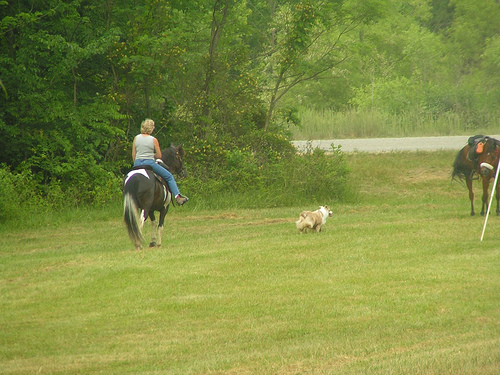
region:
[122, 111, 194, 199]
A woman riding a horse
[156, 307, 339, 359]
Grass in the photo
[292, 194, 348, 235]
A dog in the field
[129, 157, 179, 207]
Blue jeans in the photo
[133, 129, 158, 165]
A gray top on the photo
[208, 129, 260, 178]
Green vegetation in the field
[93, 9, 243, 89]
Trees in the photo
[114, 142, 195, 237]
A horse in the photo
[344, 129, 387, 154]
A road in the photo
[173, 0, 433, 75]
Bushes in the photo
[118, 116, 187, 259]
a woman on a horse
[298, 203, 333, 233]
a tan and white dog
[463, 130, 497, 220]
a brown horse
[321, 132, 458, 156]
a black top road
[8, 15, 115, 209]
a green wooded area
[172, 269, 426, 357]
a green grassy field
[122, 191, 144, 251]
a black and white tail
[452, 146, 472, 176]
a black tail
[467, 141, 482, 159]
a orange bed roll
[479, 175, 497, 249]
a white plastic pole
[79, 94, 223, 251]
horse on the ground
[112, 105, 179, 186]
person riding the horse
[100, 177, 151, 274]
tail of the horse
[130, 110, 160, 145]
head of the person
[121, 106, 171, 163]
person in a gray shirt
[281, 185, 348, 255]
dog on the grass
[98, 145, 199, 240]
black horse under person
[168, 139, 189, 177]
head of the horse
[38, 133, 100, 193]
leaves next to the horse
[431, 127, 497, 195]
horse on right side of photo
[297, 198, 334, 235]
Brown and white dog in field.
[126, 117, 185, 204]
Woman on top of horse.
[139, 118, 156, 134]
Woman's blond hair style.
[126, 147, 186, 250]
Black and white horse.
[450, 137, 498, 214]
Portion of brown horse.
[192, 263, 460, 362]
Mowed green grass of field.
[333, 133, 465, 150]
Road near forest area.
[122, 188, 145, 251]
Bushy long tail of horse.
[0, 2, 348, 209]
Tree filled forest area.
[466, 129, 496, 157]
Saddle atop brown horse.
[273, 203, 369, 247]
A dog in a field.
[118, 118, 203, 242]
A woman on a horse.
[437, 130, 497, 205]
Nobody on a horse.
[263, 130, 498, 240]
A horse looking at the dog.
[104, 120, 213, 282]
A horse trotting in a field.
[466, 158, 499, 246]
A white post in front of a horse.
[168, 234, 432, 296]
A field with brown and green grass.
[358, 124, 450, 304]
A field next to a road.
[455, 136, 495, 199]
A brown horse with a saddle.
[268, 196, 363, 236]
A tan and white Corgi.